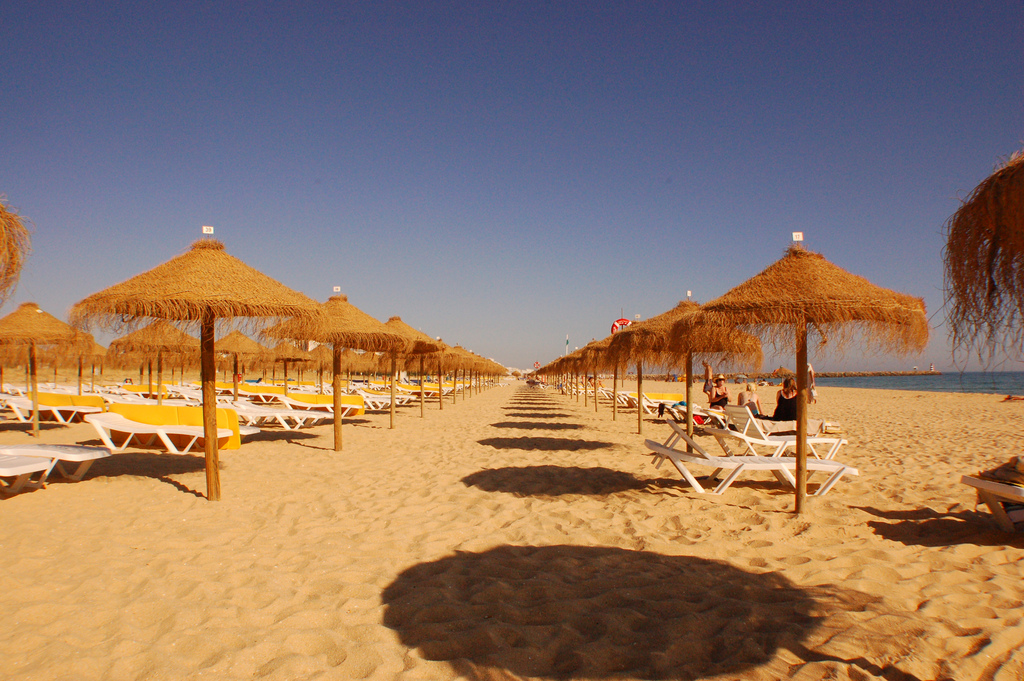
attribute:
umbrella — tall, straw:
[264, 286, 400, 454]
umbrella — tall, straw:
[359, 314, 432, 422]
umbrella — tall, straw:
[702, 223, 924, 517]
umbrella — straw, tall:
[620, 295, 764, 451]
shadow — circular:
[378, 548, 917, 676]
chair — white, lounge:
[81, 399, 230, 467]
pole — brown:
[197, 306, 224, 500]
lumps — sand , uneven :
[800, 589, 947, 679]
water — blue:
[820, 367, 1020, 394]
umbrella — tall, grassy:
[693, 244, 928, 344]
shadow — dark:
[463, 462, 682, 510]